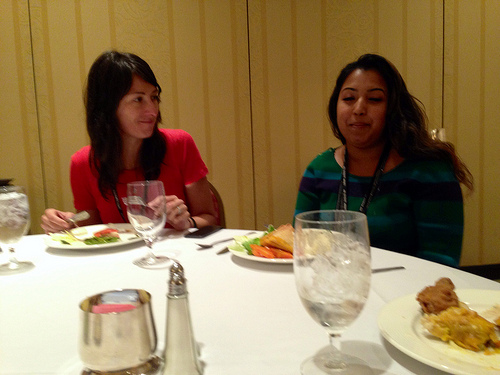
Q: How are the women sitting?
A: At a table.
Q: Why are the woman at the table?
A: To eat.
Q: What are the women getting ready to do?
A: Eat.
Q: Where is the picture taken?
A: Restaurant.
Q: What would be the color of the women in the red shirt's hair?
A: Black.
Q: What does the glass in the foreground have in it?
A: Ice.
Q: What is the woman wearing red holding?
A: Knife and fork.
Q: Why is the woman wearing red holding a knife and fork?
A: Getting ready to eat.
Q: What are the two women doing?
A: Eating.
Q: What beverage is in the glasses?
A: Water.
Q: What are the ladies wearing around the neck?
A: Lanyards.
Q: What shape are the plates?
A: Round.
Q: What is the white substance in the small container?
A: Salt.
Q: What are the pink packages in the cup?
A: Sweetener.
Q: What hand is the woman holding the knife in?
A: Right.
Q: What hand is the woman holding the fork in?
A: Left.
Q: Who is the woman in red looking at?
A: Woman in green and blue.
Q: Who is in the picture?
A: Two women.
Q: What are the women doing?
A: Having dinner.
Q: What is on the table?
A: Dinner plates and glasses.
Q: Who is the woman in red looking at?
A: The girl in green.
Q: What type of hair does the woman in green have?
A: Long and dark.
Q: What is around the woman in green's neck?
A: A lariat.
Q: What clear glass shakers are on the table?
A: Salt and pepper.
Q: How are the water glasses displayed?
A: Empty.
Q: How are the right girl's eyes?
A: Closed.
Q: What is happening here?
A: They're eating.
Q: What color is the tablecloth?
A: White.